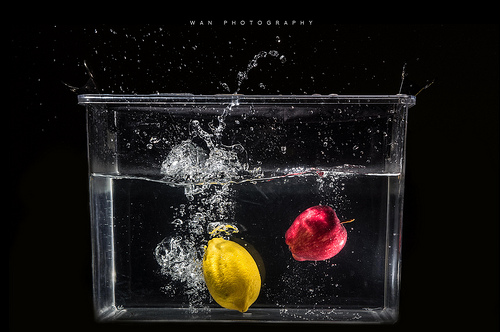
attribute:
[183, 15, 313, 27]
name — photographer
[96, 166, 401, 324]
water — clear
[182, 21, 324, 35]
letter — white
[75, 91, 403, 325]
bowl — clear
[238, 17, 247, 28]
letter — white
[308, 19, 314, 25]
letter — white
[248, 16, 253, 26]
letter — white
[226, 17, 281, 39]
letter — white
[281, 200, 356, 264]
apple — red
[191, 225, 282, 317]
lemon — unpeeled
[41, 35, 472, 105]
background — black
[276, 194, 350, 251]
apple — red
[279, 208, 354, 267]
fruit — red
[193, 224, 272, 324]
lemon — whole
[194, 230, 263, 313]
fruit — yellow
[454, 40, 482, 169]
background — black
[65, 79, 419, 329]
container — glass, clear